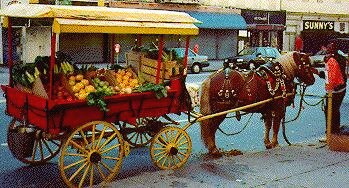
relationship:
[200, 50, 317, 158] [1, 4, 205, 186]
horse in front of kart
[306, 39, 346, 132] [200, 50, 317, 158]
human pets horse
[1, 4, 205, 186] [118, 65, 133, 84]
kart hold fruit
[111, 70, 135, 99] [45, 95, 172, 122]
fruit on cart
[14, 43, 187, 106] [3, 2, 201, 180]
vegetables on cart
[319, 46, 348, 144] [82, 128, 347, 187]
person on sidewalk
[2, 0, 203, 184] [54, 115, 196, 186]
stand has wheels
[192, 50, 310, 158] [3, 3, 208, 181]
horse pulling wagon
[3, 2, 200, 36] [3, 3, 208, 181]
yellow roof on wagon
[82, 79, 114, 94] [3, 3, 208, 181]
apples on wagon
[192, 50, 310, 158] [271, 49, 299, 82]
horse has mane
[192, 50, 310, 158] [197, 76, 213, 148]
horse has tail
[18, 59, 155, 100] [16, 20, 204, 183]
vegetables on kart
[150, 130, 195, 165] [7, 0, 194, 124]
wheel on cart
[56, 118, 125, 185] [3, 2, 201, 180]
wheel on cart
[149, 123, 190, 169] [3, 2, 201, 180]
wheel on cart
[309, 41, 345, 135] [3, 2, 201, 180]
person in front of cart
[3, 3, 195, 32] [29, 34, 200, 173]
roof of cart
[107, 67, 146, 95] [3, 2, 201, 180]
oranges in cart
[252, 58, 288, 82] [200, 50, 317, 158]
buckle on horse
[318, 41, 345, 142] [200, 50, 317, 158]
person beside horse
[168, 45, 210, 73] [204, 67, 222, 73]
car on curb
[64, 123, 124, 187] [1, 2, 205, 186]
wheel of kart